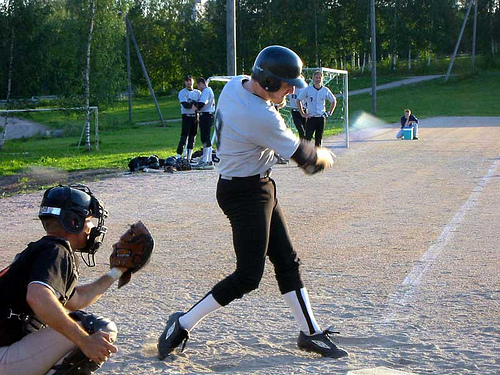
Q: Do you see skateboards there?
A: No, there are no skateboards.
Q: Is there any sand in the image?
A: Yes, there is sand.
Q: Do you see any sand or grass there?
A: Yes, there is sand.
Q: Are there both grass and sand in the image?
A: Yes, there are both sand and grass.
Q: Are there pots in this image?
A: No, there are no pots.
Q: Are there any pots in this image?
A: No, there are no pots.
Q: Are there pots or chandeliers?
A: No, there are no pots or chandeliers.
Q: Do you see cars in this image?
A: No, there are no cars.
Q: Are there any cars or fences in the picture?
A: No, there are no cars or fences.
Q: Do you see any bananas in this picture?
A: No, there are no bananas.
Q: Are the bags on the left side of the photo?
A: Yes, the bags are on the left of the image.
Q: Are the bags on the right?
A: No, the bags are on the left of the image.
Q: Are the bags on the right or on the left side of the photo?
A: The bags are on the left of the image.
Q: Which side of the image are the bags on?
A: The bags are on the left of the image.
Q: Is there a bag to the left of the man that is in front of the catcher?
A: Yes, there are bags to the left of the man.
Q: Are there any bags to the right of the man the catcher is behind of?
A: No, the bags are to the left of the man.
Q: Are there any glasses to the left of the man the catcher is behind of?
A: No, there are bags to the left of the man.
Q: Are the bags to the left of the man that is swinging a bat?
A: Yes, the bags are to the left of the man.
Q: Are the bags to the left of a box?
A: No, the bags are to the left of the man.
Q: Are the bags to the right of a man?
A: No, the bags are to the left of a man.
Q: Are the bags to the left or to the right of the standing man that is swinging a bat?
A: The bags are to the left of the man.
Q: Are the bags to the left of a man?
A: Yes, the bags are to the left of a man.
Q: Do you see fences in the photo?
A: No, there are no fences.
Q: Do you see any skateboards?
A: No, there are no skateboards.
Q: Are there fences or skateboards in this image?
A: No, there are no skateboards or fences.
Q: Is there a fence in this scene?
A: No, there are no fences.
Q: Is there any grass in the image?
A: Yes, there is grass.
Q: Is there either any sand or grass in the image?
A: Yes, there is grass.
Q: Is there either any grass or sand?
A: Yes, there is grass.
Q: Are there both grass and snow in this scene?
A: No, there is grass but no snow.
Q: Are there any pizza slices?
A: No, there are no pizza slices.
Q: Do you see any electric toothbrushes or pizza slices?
A: No, there are no pizza slices or electric toothbrushes.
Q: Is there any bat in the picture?
A: Yes, there is a bat.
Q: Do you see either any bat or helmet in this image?
A: Yes, there is a bat.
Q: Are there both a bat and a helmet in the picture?
A: Yes, there are both a bat and a helmet.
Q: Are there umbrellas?
A: No, there are no umbrellas.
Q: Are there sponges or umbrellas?
A: No, there are no umbrellas or sponges.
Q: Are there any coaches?
A: No, there are no coaches.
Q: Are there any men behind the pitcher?
A: Yes, there is a man behind the pitcher.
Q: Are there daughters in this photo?
A: No, there are no daughters.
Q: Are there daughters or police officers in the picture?
A: No, there are no daughters or police officers.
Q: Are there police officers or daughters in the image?
A: No, there are no daughters or police officers.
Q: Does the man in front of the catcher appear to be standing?
A: Yes, the man is standing.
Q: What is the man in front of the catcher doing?
A: The man is standing.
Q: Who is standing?
A: The man is standing.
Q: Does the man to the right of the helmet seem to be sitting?
A: No, the man is standing.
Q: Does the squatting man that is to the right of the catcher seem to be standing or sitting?
A: The man is standing.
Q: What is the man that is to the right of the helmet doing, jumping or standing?
A: The man is standing.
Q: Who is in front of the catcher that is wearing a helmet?
A: The man is in front of the catcher.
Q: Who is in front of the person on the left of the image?
A: The man is in front of the catcher.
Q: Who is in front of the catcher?
A: The man is in front of the catcher.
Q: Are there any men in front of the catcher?
A: Yes, there is a man in front of the catcher.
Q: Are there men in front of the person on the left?
A: Yes, there is a man in front of the catcher.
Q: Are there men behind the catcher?
A: No, the man is in front of the catcher.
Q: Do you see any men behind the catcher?
A: No, the man is in front of the catcher.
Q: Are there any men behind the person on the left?
A: No, the man is in front of the catcher.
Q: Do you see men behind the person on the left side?
A: No, the man is in front of the catcher.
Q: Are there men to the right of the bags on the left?
A: Yes, there is a man to the right of the bags.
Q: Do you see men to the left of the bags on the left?
A: No, the man is to the right of the bags.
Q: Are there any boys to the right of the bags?
A: No, there is a man to the right of the bags.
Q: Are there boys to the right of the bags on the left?
A: No, there is a man to the right of the bags.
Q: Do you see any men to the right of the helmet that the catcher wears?
A: Yes, there is a man to the right of the helmet.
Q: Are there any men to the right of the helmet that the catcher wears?
A: Yes, there is a man to the right of the helmet.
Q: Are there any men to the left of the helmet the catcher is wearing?
A: No, the man is to the right of the helmet.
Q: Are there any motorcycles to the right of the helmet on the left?
A: No, there is a man to the right of the helmet.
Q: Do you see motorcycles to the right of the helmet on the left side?
A: No, there is a man to the right of the helmet.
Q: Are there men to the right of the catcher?
A: Yes, there is a man to the right of the catcher.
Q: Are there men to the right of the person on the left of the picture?
A: Yes, there is a man to the right of the catcher.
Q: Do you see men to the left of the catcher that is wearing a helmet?
A: No, the man is to the right of the catcher.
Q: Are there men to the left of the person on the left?
A: No, the man is to the right of the catcher.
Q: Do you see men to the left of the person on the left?
A: No, the man is to the right of the catcher.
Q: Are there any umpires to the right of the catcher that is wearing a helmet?
A: No, there is a man to the right of the catcher.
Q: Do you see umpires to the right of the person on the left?
A: No, there is a man to the right of the catcher.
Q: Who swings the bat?
A: The man swings the bat.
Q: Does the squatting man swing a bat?
A: Yes, the man swings a bat.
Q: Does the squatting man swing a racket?
A: No, the man swings a bat.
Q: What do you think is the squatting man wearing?
A: The man is wearing a helmet.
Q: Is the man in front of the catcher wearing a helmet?
A: Yes, the man is wearing a helmet.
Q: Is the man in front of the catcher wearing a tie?
A: No, the man is wearing a helmet.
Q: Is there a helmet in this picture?
A: Yes, there is a helmet.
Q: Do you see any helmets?
A: Yes, there is a helmet.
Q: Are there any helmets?
A: Yes, there is a helmet.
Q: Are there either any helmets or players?
A: Yes, there is a helmet.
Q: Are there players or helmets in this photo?
A: Yes, there is a helmet.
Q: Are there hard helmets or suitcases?
A: Yes, there is a hard helmet.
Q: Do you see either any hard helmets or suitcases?
A: Yes, there is a hard helmet.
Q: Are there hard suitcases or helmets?
A: Yes, there is a hard helmet.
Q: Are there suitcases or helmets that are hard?
A: Yes, the helmet is hard.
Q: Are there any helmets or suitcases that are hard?
A: Yes, the helmet is hard.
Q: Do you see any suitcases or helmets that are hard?
A: Yes, the helmet is hard.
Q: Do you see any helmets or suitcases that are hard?
A: Yes, the helmet is hard.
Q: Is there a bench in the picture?
A: No, there are no benches.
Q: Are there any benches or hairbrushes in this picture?
A: No, there are no benches or hairbrushes.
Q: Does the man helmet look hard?
A: Yes, the helmet is hard.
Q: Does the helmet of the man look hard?
A: Yes, the helmet is hard.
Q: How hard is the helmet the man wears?
A: The helmet is hard.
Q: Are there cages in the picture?
A: No, there are no cages.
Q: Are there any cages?
A: No, there are no cages.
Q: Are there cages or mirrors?
A: No, there are no cages or mirrors.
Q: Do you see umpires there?
A: No, there are no umpires.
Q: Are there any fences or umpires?
A: No, there are no umpires or fences.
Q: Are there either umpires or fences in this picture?
A: No, there are no umpires or fences.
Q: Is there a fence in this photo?
A: No, there are no fences.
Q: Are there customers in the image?
A: No, there are no customers.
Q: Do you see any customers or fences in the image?
A: No, there are no customers or fences.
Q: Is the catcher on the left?
A: Yes, the catcher is on the left of the image.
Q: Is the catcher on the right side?
A: No, the catcher is on the left of the image.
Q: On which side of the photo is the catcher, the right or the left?
A: The catcher is on the left of the image.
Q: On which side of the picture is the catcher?
A: The catcher is on the left of the image.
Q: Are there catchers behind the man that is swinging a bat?
A: Yes, there is a catcher behind the man.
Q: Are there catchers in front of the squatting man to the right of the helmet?
A: No, the catcher is behind the man.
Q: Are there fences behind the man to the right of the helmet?
A: No, there is a catcher behind the man.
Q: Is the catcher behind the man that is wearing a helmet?
A: Yes, the catcher is behind the man.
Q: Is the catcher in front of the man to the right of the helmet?
A: No, the catcher is behind the man.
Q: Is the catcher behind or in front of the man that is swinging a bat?
A: The catcher is behind the man.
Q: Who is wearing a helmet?
A: The catcher is wearing a helmet.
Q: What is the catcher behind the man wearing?
A: The catcher is wearing a helmet.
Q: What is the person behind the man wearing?
A: The catcher is wearing a helmet.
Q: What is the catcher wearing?
A: The catcher is wearing a helmet.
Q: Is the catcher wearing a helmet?
A: Yes, the catcher is wearing a helmet.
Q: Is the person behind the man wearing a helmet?
A: Yes, the catcher is wearing a helmet.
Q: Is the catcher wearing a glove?
A: No, the catcher is wearing a helmet.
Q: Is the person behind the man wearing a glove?
A: No, the catcher is wearing a helmet.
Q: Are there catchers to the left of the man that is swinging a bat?
A: Yes, there is a catcher to the left of the man.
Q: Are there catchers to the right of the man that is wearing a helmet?
A: No, the catcher is to the left of the man.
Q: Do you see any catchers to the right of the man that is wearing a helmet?
A: No, the catcher is to the left of the man.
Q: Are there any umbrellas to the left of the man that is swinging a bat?
A: No, there is a catcher to the left of the man.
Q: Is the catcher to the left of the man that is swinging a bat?
A: Yes, the catcher is to the left of the man.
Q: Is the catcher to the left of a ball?
A: No, the catcher is to the left of the man.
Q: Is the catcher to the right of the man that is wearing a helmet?
A: No, the catcher is to the left of the man.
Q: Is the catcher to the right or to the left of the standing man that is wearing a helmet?
A: The catcher is to the left of the man.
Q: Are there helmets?
A: Yes, there is a helmet.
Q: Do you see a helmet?
A: Yes, there is a helmet.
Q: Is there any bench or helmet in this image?
A: Yes, there is a helmet.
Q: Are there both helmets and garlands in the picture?
A: No, there is a helmet but no garlands.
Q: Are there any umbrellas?
A: No, there are no umbrellas.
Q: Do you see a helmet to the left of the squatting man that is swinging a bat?
A: Yes, there is a helmet to the left of the man.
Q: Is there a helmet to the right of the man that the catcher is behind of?
A: No, the helmet is to the left of the man.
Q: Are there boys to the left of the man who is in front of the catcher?
A: No, there is a helmet to the left of the man.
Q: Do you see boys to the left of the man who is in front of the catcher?
A: No, there is a helmet to the left of the man.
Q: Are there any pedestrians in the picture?
A: No, there are no pedestrians.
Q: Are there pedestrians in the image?
A: No, there are no pedestrians.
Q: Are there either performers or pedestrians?
A: No, there are no pedestrians or performers.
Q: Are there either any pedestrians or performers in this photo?
A: No, there are no pedestrians or performers.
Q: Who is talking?
A: The man is talking.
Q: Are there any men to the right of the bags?
A: Yes, there is a man to the right of the bags.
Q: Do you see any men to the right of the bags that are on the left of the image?
A: Yes, there is a man to the right of the bags.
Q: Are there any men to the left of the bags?
A: No, the man is to the right of the bags.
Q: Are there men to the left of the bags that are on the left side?
A: No, the man is to the right of the bags.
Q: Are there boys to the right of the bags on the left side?
A: No, there is a man to the right of the bags.